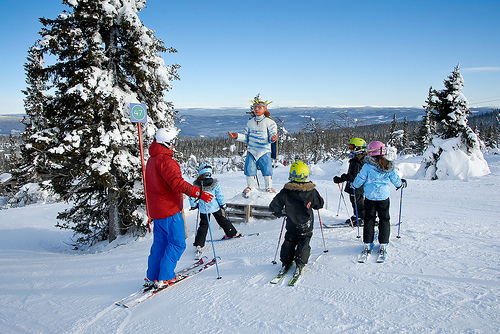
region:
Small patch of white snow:
[336, 293, 362, 313]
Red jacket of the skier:
[155, 169, 171, 197]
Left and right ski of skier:
[193, 260, 204, 275]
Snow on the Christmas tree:
[80, 70, 106, 86]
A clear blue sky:
[312, 27, 383, 60]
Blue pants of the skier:
[153, 222, 174, 267]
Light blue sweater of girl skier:
[365, 165, 380, 185]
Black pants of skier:
[280, 231, 307, 256]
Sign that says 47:
[126, 100, 146, 127]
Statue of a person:
[226, 93, 279, 193]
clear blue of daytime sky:
[180, 2, 498, 104]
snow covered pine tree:
[20, 0, 179, 240]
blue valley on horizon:
[171, 96, 497, 195]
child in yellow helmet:
[269, 159, 324, 285]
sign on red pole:
[129, 102, 147, 186]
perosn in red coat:
[142, 126, 213, 288]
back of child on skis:
[349, 141, 406, 263]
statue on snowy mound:
[227, 96, 280, 202]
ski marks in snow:
[80, 230, 496, 332]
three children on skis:
[269, 135, 406, 287]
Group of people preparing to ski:
[111, 100, 406, 311]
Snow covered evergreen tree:
[12, 1, 179, 251]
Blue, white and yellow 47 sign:
[125, 100, 149, 122]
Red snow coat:
[146, 141, 191, 217]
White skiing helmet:
[154, 126, 177, 146]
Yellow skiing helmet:
[288, 159, 308, 183]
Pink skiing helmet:
[366, 139, 386, 154]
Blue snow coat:
[350, 155, 399, 200]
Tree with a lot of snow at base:
[418, 64, 492, 176]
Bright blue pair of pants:
[146, 215, 186, 279]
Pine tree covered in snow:
[40, 3, 137, 250]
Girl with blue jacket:
[367, 140, 393, 245]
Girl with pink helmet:
[368, 141, 398, 248]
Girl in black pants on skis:
[365, 142, 394, 263]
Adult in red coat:
[152, 126, 181, 288]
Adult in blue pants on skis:
[147, 126, 194, 285]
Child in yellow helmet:
[285, 163, 315, 287]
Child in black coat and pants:
[285, 162, 317, 279]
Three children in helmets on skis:
[272, 137, 407, 284]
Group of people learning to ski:
[140, 95, 407, 280]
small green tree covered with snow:
[40, 0, 188, 248]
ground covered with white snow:
[364, 276, 452, 321]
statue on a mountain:
[227, 97, 288, 195]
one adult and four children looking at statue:
[120, 120, 411, 270]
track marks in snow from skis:
[77, 301, 138, 331]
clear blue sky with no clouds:
[275, 25, 405, 64]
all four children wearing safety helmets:
[195, 133, 404, 183]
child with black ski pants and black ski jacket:
[277, 177, 331, 269]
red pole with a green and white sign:
[123, 95, 162, 234]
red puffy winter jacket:
[145, 140, 195, 217]